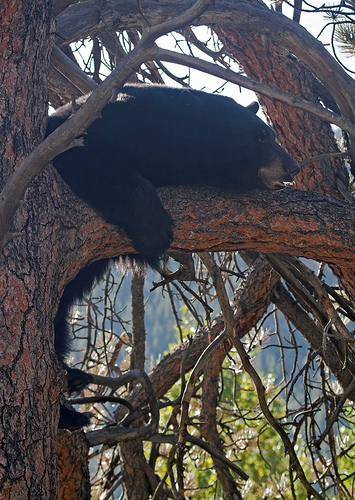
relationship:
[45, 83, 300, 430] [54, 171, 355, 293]
bear holding limb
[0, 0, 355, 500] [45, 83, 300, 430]
pine with bear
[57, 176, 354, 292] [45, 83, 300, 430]
limb with bear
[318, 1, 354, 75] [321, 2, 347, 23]
branch with pine needles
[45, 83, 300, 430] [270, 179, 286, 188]
bear with tongue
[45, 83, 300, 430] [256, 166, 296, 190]
bear has mouth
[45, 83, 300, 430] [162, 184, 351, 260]
bear hugging tree branch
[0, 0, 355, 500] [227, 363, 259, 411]
pine with foliage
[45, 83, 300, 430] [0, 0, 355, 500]
bear hugging pine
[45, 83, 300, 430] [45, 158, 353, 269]
bear resting on limb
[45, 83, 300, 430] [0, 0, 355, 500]
bear climbing pine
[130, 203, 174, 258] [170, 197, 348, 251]
paw resting on limb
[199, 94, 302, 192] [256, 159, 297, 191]
head with mouth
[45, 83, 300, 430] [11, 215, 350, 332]
bear relaxing in pine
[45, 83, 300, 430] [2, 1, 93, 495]
bear climbing in tree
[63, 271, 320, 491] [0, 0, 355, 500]
branches in pine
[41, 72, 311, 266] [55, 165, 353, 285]
bear lazing on limb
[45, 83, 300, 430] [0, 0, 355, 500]
bear relaxing in pine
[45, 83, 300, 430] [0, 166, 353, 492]
bear hugging pine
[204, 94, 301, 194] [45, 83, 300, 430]
head of bear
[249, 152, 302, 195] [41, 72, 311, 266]
mouth of bear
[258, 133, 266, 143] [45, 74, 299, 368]
eye of bear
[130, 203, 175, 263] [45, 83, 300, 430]
paw of bear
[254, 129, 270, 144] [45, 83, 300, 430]
eye of bear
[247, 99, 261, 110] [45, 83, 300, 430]
ear of bear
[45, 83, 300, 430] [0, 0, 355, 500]
bear on pine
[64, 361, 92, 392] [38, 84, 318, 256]
foot of bear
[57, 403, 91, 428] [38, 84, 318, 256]
foot of bear